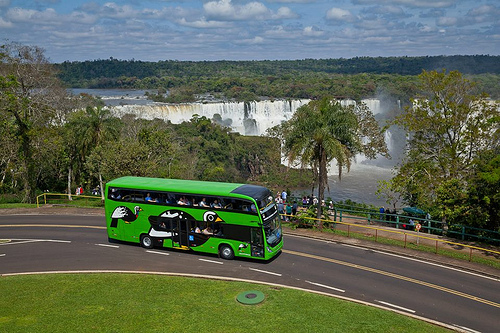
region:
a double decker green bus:
[103, 175, 283, 262]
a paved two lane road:
[0, 207, 499, 331]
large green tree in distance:
[279, 98, 359, 205]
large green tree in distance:
[408, 68, 495, 218]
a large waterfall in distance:
[82, 98, 497, 175]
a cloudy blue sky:
[2, 0, 499, 63]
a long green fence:
[287, 198, 499, 248]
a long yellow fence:
[278, 211, 498, 267]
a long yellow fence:
[33, 189, 102, 209]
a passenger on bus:
[197, 197, 209, 207]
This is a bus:
[89, 165, 333, 286]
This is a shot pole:
[431, 231, 442, 262]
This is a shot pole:
[468, 242, 478, 269]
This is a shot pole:
[40, 190, 51, 207]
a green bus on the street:
[102, 177, 286, 261]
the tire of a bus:
[218, 243, 233, 260]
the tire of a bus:
[139, 234, 153, 249]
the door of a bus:
[248, 226, 265, 258]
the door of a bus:
[170, 218, 190, 250]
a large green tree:
[259, 92, 389, 223]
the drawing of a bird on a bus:
[109, 202, 143, 231]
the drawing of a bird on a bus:
[141, 209, 226, 252]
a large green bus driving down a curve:
[101, 176, 288, 266]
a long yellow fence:
[35, 190, 498, 271]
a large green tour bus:
[97, 186, 288, 256]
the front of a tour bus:
[245, 191, 293, 269]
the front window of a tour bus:
[252, 212, 287, 237]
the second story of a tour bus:
[162, 192, 249, 212]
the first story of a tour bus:
[161, 211, 246, 241]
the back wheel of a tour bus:
[134, 231, 158, 252]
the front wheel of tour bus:
[212, 243, 234, 258]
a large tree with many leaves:
[267, 105, 365, 169]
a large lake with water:
[228, 92, 278, 133]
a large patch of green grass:
[51, 282, 126, 327]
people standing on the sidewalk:
[275, 191, 326, 221]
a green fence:
[337, 205, 487, 235]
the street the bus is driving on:
[5, 220, 495, 305]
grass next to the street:
[0, 275, 377, 330]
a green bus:
[100, 175, 280, 257]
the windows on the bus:
[107, 186, 249, 206]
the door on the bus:
[250, 225, 265, 250]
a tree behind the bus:
[290, 90, 340, 205]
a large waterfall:
[116, 91, 406, 137]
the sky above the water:
[7, 5, 494, 45]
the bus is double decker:
[115, 165, 275, 270]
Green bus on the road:
[96, 167, 291, 275]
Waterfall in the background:
[123, 98, 411, 169]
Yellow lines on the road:
[310, 252, 350, 272]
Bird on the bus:
[108, 202, 144, 233]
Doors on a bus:
[169, 216, 191, 251]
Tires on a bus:
[219, 244, 233, 261]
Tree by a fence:
[275, 89, 390, 231]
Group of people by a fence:
[276, 187, 343, 229]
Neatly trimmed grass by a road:
[98, 274, 200, 331]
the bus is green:
[102, 173, 283, 263]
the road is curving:
[8, 210, 361, 308]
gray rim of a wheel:
[220, 245, 234, 256]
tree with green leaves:
[404, 76, 492, 158]